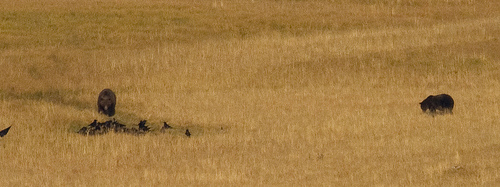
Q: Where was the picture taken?
A: The field.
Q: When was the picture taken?
A: Summer.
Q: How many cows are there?
A: Two.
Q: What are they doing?
A: Grazing.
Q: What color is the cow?
A: Black.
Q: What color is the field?
A: Brown.